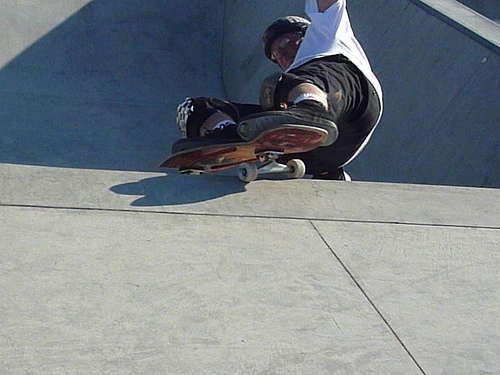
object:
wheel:
[237, 162, 257, 183]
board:
[157, 123, 329, 182]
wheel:
[287, 159, 306, 179]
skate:
[158, 104, 340, 182]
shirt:
[283, 0, 384, 176]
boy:
[170, 0, 384, 173]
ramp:
[2, 160, 497, 371]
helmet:
[261, 15, 311, 64]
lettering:
[285, 16, 312, 25]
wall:
[2, 1, 498, 185]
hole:
[239, 122, 249, 137]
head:
[261, 15, 312, 72]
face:
[271, 33, 301, 70]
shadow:
[109, 170, 247, 206]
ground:
[0, 164, 497, 372]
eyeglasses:
[271, 34, 302, 60]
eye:
[273, 50, 280, 58]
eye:
[280, 38, 289, 47]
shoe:
[171, 124, 246, 156]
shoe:
[236, 109, 340, 147]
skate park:
[4, 4, 498, 373]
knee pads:
[258, 70, 284, 110]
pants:
[175, 53, 381, 174]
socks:
[294, 92, 328, 111]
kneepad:
[175, 96, 194, 138]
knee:
[174, 96, 217, 133]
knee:
[259, 72, 309, 110]